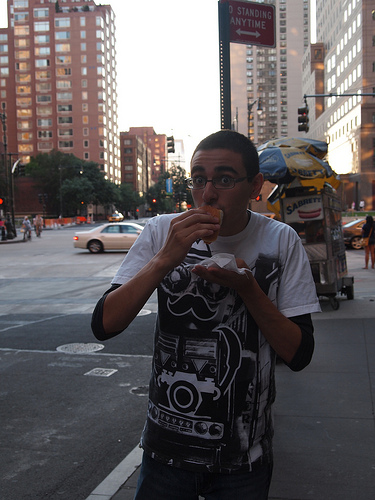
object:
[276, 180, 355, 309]
hotdog stand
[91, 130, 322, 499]
man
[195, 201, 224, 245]
hot dog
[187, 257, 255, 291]
hand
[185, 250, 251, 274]
napkin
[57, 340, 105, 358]
sewer cover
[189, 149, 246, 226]
face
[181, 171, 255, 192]
glasses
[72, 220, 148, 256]
car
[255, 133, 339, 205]
umbrellas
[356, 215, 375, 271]
woman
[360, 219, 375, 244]
shirt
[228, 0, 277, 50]
sign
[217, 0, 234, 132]
pole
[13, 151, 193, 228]
trees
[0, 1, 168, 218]
buildings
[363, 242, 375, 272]
pants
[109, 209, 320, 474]
shirt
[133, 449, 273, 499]
jeans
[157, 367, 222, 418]
camera print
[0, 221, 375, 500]
sidewalk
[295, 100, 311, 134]
traffic light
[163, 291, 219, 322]
mustache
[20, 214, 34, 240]
person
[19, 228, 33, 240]
bicycle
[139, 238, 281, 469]
graphics